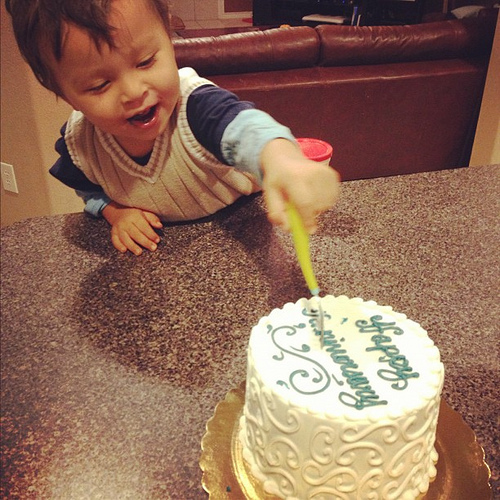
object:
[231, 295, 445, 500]
cake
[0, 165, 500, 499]
table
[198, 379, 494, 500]
cardboard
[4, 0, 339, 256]
boy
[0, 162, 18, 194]
outlet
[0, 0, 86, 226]
wall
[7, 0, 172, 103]
hair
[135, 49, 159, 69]
eye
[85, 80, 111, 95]
eye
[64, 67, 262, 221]
vest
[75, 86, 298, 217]
shirt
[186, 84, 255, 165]
sleeve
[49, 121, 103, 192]
sleeve